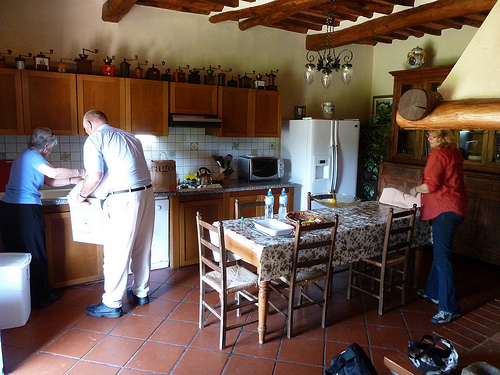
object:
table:
[209, 199, 436, 345]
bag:
[150, 160, 177, 193]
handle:
[158, 151, 168, 162]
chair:
[194, 211, 259, 351]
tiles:
[107, 313, 166, 343]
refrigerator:
[286, 119, 361, 212]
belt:
[107, 183, 152, 196]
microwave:
[237, 156, 284, 186]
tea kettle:
[195, 167, 213, 186]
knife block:
[212, 166, 234, 187]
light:
[304, 12, 354, 89]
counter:
[0, 176, 298, 208]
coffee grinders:
[0, 46, 281, 93]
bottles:
[264, 189, 274, 219]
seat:
[202, 264, 259, 295]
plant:
[356, 103, 393, 202]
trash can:
[0, 252, 33, 330]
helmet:
[406, 330, 459, 374]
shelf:
[1, 67, 280, 93]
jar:
[406, 45, 427, 69]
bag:
[324, 343, 380, 375]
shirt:
[419, 143, 468, 221]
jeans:
[425, 212, 462, 314]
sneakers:
[86, 301, 123, 319]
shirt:
[0, 148, 51, 207]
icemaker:
[312, 155, 331, 182]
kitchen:
[1, 0, 499, 374]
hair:
[424, 129, 460, 150]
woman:
[409, 129, 466, 325]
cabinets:
[0, 69, 26, 136]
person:
[75, 110, 156, 318]